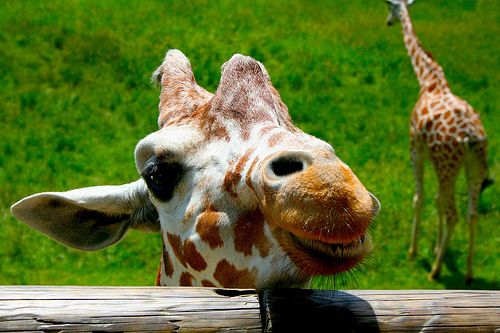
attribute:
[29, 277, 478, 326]
fence — long, wooden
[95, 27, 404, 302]
giraffe — brown 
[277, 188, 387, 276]
mouth — orange, brown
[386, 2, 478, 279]
giraffe — white, brown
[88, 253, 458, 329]
beam — wooden, long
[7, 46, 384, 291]
giraffe — young, white, brown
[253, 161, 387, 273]
mouth — giraffe, open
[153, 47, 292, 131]
horns — small